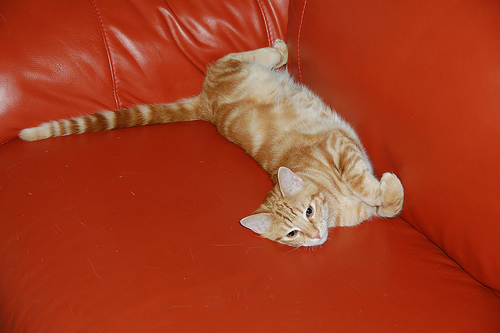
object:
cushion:
[0, 120, 500, 333]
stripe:
[42, 123, 54, 139]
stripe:
[51, 121, 69, 137]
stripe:
[68, 116, 81, 137]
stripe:
[84, 115, 92, 133]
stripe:
[83, 115, 106, 132]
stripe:
[102, 110, 117, 129]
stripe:
[116, 106, 130, 128]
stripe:
[140, 104, 162, 125]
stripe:
[158, 102, 172, 124]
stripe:
[170, 99, 190, 122]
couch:
[0, 0, 500, 333]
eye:
[304, 203, 315, 220]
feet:
[272, 39, 285, 46]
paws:
[381, 173, 397, 185]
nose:
[301, 221, 321, 239]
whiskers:
[286, 246, 323, 253]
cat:
[19, 39, 406, 248]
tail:
[18, 96, 200, 142]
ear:
[277, 166, 304, 197]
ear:
[239, 212, 273, 236]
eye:
[284, 230, 298, 238]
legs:
[373, 187, 404, 217]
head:
[238, 166, 328, 249]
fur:
[218, 77, 317, 163]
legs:
[253, 46, 288, 69]